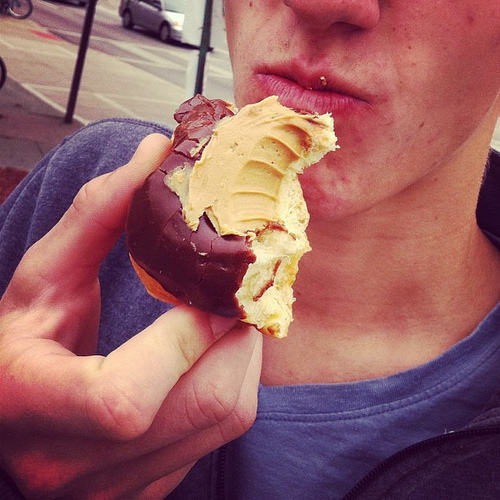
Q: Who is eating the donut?
A: The teenager.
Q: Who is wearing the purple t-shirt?
A: Teenage boy.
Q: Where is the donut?
A: In the right hand.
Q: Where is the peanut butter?
A: On the donut.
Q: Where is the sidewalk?
A: In the city.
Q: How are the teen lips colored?
A: Red.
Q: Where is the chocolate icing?
A: On the donut.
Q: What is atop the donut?
A: Peanut butter.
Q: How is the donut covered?
A: With chocolate.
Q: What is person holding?
A: Donut.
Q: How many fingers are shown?
A: Four.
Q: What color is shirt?
A: Purple.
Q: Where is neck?
A: On person.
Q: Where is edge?
A: On pastry.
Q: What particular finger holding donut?
A: Thumb.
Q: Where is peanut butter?
A: On donut.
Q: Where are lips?
A: Near donut.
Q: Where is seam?
A: On neckline.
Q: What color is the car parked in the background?
A: Silver.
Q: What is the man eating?
A: A chocolate frosted pastry.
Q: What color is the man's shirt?
A: Blue.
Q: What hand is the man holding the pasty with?
A: Right hand.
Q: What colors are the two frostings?
A: Black and yellow.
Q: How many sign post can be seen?
A: Two.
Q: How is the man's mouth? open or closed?
A: Closed.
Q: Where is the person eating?
A: Street.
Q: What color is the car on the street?
A: Silver.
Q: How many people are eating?
A: One.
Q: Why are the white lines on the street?
A: Crosswalk.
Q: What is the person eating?
A: Doughnut.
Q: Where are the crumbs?
A: On the person's mouth.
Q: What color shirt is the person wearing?
A: Blue.